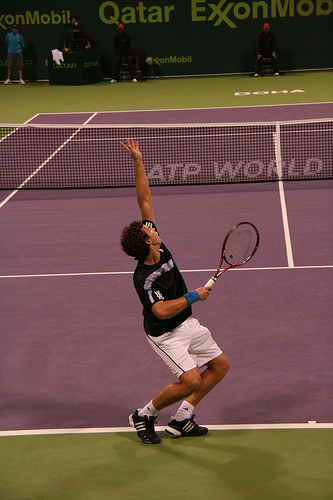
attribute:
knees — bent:
[177, 357, 230, 387]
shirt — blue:
[4, 30, 26, 53]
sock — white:
[172, 399, 193, 420]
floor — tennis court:
[0, 63, 328, 496]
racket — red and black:
[191, 229, 275, 292]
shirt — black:
[129, 253, 201, 312]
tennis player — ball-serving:
[111, 133, 268, 446]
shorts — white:
[142, 315, 220, 379]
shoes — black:
[124, 404, 212, 444]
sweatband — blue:
[181, 288, 203, 307]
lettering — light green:
[48, 7, 63, 28]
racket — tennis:
[187, 220, 261, 297]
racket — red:
[191, 217, 278, 290]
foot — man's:
[127, 405, 160, 446]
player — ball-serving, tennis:
[83, 135, 332, 443]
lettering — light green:
[94, 1, 177, 25]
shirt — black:
[132, 218, 191, 335]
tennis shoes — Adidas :
[127, 406, 207, 444]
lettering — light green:
[98, 0, 176, 24]